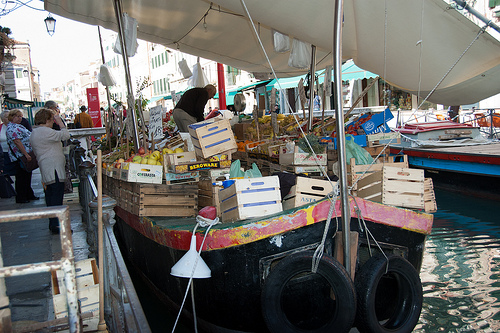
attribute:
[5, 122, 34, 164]
shirt — large, floral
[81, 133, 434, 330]
boat — one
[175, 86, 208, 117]
shirt — large, black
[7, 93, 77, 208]
people — some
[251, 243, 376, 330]
tire — black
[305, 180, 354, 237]
rope — white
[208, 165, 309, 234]
crate — brown, wooden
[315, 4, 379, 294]
pole — silver, metal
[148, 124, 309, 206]
boxes — wooden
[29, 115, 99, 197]
shirt — large, khaki, woman's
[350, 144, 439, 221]
produce box — small, wooden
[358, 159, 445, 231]
produce box — empty, wooden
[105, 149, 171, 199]
cardboard box — full, produce box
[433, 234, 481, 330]
water — rippling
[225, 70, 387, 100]
building awning — green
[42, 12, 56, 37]
light — suspended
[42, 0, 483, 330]
boat — large, messy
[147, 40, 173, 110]
building — multi-story, tall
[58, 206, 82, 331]
bar — rusted, metal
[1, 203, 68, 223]
bar — rusted, metal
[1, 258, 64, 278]
bar — rusted, metal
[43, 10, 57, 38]
lamp — off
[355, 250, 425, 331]
tire — rubber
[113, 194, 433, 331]
paint — red, yellow, black, white, gray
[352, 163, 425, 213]
fruit crate — empty, wooden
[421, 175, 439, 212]
fruit crate — empty, wooden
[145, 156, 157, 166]
apple — fresh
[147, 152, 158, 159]
apple — fresh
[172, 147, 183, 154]
apple — fresh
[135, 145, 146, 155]
apple — fresh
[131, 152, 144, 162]
apple — fresh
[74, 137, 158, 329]
railing — iron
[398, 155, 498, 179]
stripes — blue, red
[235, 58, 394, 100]
awnings — teal, tan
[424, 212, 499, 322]
water — calm